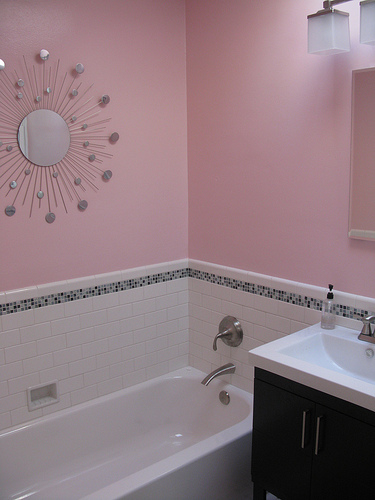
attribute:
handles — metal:
[296, 406, 325, 457]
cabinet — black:
[251, 367, 370, 497]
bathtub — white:
[0, 343, 269, 499]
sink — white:
[256, 313, 374, 395]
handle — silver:
[207, 319, 243, 357]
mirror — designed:
[349, 70, 374, 235]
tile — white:
[163, 293, 173, 309]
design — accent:
[2, 43, 122, 227]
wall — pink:
[4, 2, 375, 302]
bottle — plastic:
[321, 296, 333, 331]